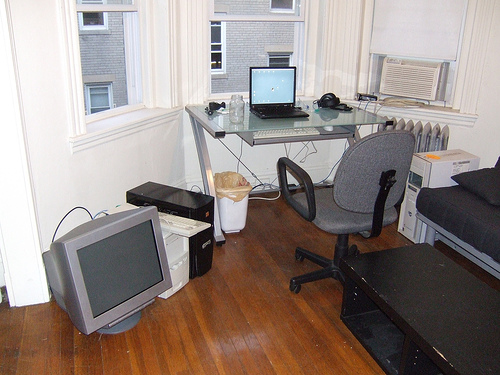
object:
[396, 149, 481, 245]
computer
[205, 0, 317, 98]
window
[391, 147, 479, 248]
flowers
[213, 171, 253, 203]
bag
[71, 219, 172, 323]
monitor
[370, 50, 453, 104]
heater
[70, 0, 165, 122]
window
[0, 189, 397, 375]
floor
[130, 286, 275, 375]
wood paneling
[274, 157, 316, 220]
handle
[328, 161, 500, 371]
table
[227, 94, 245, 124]
jar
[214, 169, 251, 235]
garbage can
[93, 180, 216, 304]
computers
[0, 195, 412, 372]
dust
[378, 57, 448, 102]
air conditioner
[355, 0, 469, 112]
window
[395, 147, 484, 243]
tower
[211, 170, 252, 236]
can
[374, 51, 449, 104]
unit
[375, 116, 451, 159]
radiator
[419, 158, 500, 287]
sofa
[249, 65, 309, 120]
computer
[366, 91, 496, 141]
wall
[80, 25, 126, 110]
building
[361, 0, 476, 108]
blinds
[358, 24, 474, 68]
closed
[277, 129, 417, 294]
chair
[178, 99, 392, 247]
desk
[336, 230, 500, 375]
box